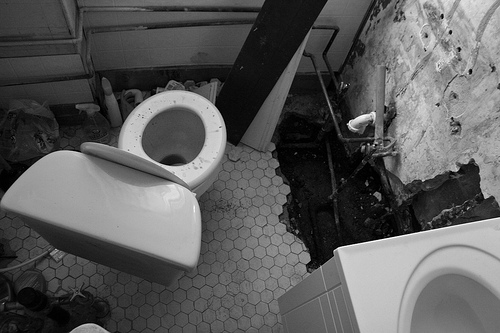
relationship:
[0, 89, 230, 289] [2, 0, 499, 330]
toilet in bathroom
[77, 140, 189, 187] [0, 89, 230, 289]
lid up on toilet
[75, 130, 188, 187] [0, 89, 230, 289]
lid up on toilet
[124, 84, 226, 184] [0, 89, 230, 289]
seat down on toilet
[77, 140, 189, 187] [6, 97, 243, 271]
lid up on toilet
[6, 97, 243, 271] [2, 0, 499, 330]
toilet in bathroom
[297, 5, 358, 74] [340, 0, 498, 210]
plaster off wall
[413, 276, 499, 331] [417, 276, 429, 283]
sink seen edge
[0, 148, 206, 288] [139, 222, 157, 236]
tank seen part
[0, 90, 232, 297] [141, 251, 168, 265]
tank has edge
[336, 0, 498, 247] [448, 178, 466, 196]
wall has part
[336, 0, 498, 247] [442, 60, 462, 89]
wall has edge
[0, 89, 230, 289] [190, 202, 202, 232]
toilet has edge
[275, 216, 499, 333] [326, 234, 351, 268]
sink has edge